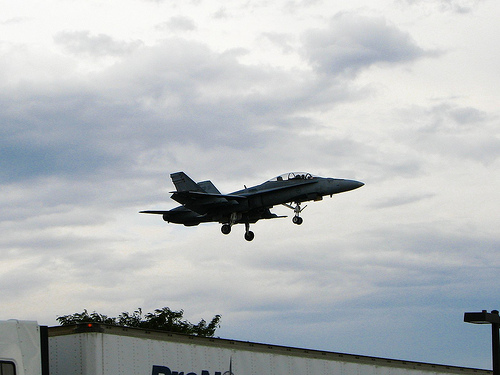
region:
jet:
[139, 159, 374, 248]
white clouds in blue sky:
[32, 71, 76, 133]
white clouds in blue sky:
[376, 214, 433, 274]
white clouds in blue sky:
[303, 257, 363, 321]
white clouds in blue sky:
[207, 266, 276, 303]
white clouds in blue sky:
[74, 210, 115, 261]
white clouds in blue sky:
[312, 60, 369, 118]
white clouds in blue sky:
[378, 139, 433, 201]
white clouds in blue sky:
[235, 77, 293, 144]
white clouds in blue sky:
[116, 89, 174, 146]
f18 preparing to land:
[154, 159, 351, 234]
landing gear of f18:
[245, 220, 251, 246]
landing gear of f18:
[218, 224, 237, 241]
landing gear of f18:
[293, 213, 308, 224]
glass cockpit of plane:
[265, 165, 320, 177]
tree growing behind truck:
[65, 290, 210, 340]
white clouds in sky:
[90, 61, 202, 147]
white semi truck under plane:
[11, 334, 391, 372]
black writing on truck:
[138, 344, 213, 373]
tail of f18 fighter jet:
[174, 159, 225, 207]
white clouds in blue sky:
[282, 300, 332, 334]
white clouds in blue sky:
[338, 266, 376, 306]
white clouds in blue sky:
[108, 267, 168, 292]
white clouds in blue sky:
[384, 150, 409, 187]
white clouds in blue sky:
[311, 282, 338, 314]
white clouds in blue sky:
[60, 244, 100, 262]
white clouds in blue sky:
[60, 175, 101, 222]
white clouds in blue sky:
[154, 72, 189, 101]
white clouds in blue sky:
[235, 93, 273, 142]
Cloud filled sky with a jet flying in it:
[0, 0, 495, 370]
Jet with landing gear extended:
[135, 169, 365, 243]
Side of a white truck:
[2, 317, 497, 374]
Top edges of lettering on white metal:
[148, 363, 236, 373]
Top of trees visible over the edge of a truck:
[55, 305, 225, 335]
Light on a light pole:
[460, 303, 498, 373]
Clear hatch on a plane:
[267, 170, 314, 183]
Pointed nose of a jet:
[320, 174, 367, 199]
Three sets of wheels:
[216, 211, 305, 243]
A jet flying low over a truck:
[0, 165, 498, 373]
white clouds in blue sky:
[72, 52, 110, 78]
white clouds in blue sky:
[421, 163, 455, 199]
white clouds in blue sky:
[328, 262, 405, 301]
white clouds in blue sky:
[224, 282, 344, 335]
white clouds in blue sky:
[45, 100, 111, 193]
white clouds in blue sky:
[255, 73, 334, 114]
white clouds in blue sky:
[39, 27, 118, 101]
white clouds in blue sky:
[36, 179, 97, 232]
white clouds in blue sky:
[175, 33, 238, 106]